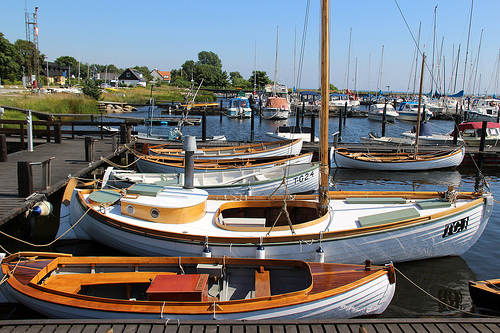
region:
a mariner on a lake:
[13, 8, 494, 330]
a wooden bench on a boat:
[242, 268, 274, 300]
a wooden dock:
[0, 320, 498, 332]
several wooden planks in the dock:
[4, 325, 79, 331]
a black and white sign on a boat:
[441, 217, 476, 239]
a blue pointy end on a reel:
[30, 204, 40, 211]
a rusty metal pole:
[310, 1, 337, 188]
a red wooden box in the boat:
[149, 271, 210, 296]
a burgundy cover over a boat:
[460, 119, 498, 131]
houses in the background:
[114, 60, 171, 90]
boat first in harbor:
[7, 245, 396, 316]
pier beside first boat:
[7, 312, 499, 329]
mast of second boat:
[308, 5, 343, 204]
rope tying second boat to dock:
[3, 206, 88, 250]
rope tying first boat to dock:
[391, 262, 491, 331]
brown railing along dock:
[5, 114, 121, 149]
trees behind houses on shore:
[2, 29, 227, 90]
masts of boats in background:
[255, 12, 484, 117]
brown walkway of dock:
[2, 128, 116, 223]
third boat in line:
[100, 151, 322, 191]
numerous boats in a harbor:
[9, 82, 494, 323]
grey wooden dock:
[6, 115, 155, 226]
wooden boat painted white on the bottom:
[12, 250, 383, 318]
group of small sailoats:
[60, 125, 458, 312]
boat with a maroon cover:
[451, 114, 496, 150]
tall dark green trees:
[174, 50, 271, 97]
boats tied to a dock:
[26, 119, 457, 317]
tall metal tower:
[20, 7, 45, 82]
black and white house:
[101, 68, 141, 87]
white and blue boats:
[296, 87, 426, 127]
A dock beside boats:
[8, 113, 160, 255]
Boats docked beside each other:
[14, 123, 396, 331]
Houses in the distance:
[68, 55, 199, 97]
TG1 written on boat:
[388, 217, 497, 262]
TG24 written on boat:
[271, 163, 349, 198]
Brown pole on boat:
[309, 0, 369, 269]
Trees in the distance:
[163, 46, 268, 93]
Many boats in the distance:
[198, 57, 493, 133]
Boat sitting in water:
[323, 138, 485, 190]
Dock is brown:
[3, 118, 128, 216]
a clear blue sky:
[0, 1, 499, 102]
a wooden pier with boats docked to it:
[0, 116, 142, 243]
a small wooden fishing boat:
[0, 253, 410, 322]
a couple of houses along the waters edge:
[91, 67, 173, 89]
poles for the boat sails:
[243, 2, 498, 204]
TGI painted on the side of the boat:
[441, 214, 473, 240]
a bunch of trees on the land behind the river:
[168, 48, 278, 93]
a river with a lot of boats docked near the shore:
[25, 90, 496, 319]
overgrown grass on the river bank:
[0, 91, 100, 126]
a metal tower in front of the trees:
[22, 5, 41, 89]